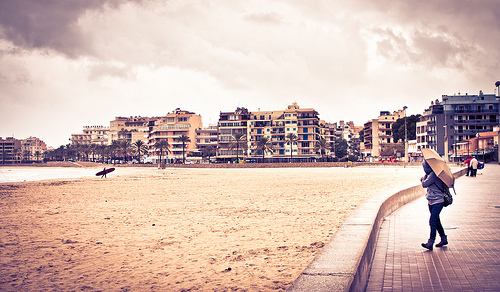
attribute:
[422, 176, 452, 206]
sweater — blue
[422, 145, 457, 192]
gray umbrella — grey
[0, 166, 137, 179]
water — colorless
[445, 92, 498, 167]
building — blue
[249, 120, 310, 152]
window — blue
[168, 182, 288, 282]
floor — brown